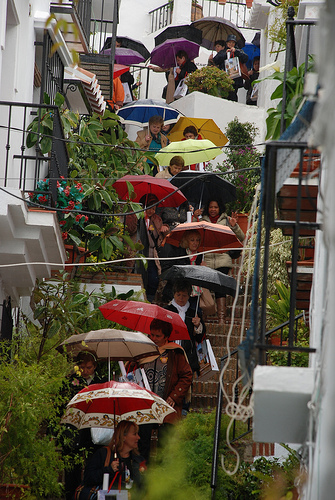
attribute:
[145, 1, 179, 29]
railing — black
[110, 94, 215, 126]
umbrellas — blue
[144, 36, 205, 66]
umbrella — purple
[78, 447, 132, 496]
purse — brown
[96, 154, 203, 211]
umbrella — black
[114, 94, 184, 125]
umbrella — blue, white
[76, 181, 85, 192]
flower — green leaved 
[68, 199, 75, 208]
flower — green leaved 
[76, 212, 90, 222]
flower — green leaved 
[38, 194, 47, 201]
flower — green leaved 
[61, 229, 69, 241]
flower — green leaved 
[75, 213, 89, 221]
blossom — red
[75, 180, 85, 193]
blossom — red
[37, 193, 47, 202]
blossom — red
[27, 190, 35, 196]
blossom — red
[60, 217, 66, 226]
blossom — red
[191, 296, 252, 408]
stairs — red, brick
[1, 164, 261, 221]
cable — black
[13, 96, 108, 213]
balcony — black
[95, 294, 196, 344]
umbrella — red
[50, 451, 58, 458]
leaf — Bright green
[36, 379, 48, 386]
leaf — Bright green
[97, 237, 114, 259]
leaf — Bright green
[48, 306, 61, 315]
leaf — Bright green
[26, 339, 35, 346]
leaf — Bright green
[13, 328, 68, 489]
tree — Bright green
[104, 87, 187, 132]
umbrella — black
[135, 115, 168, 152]
blonde woman — Blond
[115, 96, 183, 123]
umbrella — blue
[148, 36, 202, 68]
umbrella — purple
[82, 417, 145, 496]
woman — red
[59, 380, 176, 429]
umbrella — red, white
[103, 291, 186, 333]
umbrellas — red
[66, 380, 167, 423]
umbrellas — red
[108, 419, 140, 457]
hair — light brown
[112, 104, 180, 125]
trim — white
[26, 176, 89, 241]
flowers — red